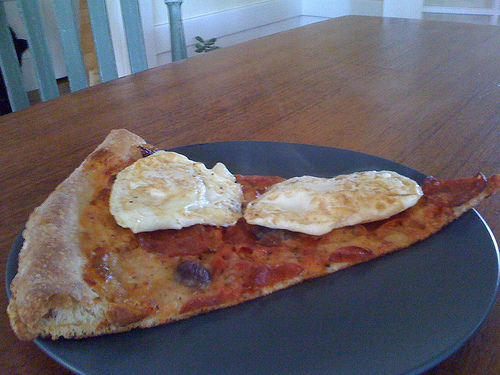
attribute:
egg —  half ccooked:
[248, 159, 438, 250]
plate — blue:
[67, 127, 498, 358]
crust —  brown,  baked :
[6, 126, 129, 345]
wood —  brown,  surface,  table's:
[239, 34, 479, 124]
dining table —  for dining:
[12, 11, 497, 370]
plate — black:
[73, 149, 498, 373]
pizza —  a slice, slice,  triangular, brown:
[15, 126, 498, 343]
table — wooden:
[0, 8, 495, 373]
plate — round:
[16, 120, 496, 367]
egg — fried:
[245, 166, 417, 233]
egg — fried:
[108, 147, 239, 227]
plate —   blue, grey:
[4, 135, 498, 374]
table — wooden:
[111, 11, 497, 126]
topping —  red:
[97, 161, 498, 311]